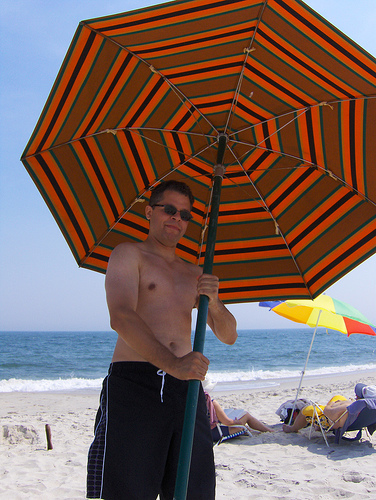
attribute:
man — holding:
[80, 157, 258, 499]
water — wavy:
[2, 331, 374, 374]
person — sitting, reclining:
[276, 373, 373, 441]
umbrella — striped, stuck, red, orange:
[12, 3, 375, 300]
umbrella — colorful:
[254, 283, 375, 347]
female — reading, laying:
[193, 388, 279, 446]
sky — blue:
[2, 0, 375, 328]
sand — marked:
[6, 374, 374, 499]